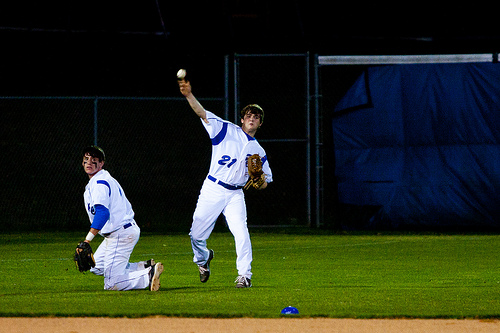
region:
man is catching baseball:
[167, 48, 274, 273]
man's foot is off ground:
[190, 231, 229, 293]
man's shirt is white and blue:
[204, 108, 256, 193]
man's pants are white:
[178, 174, 265, 274]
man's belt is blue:
[193, 159, 255, 197]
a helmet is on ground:
[273, 283, 298, 325]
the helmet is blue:
[268, 301, 312, 324]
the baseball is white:
[170, 51, 197, 91]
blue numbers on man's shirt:
[215, 146, 241, 171]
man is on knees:
[53, 151, 155, 315]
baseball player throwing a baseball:
[166, 52, 290, 293]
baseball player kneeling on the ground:
[63, 129, 191, 308]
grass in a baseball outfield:
[54, 227, 481, 308]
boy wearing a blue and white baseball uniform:
[169, 50, 297, 274]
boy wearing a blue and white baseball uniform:
[65, 110, 174, 305]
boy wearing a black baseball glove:
[61, 135, 171, 306]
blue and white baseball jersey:
[191, 62, 300, 274]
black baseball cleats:
[179, 231, 275, 301]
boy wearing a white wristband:
[66, 137, 136, 277]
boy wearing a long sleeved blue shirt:
[72, 137, 147, 279]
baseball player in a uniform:
[136, 48, 308, 292]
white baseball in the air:
[166, 56, 196, 79]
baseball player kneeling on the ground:
[51, 133, 171, 292]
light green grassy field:
[72, 213, 472, 319]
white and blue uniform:
[178, 85, 288, 291]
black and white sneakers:
[194, 242, 250, 312]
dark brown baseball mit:
[234, 146, 281, 199]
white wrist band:
[68, 218, 119, 270]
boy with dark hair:
[65, 134, 126, 193]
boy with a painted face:
[54, 136, 118, 199]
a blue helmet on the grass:
[269, 296, 308, 322]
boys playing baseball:
[39, 57, 288, 279]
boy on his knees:
[44, 140, 171, 291]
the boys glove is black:
[51, 234, 111, 280]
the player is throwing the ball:
[146, 45, 283, 308]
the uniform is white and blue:
[149, 61, 299, 291]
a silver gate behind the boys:
[66, 37, 327, 262]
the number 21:
[197, 142, 242, 184]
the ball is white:
[155, 57, 194, 112]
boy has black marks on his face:
[65, 137, 102, 174]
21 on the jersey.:
[216, 144, 248, 179]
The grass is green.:
[302, 240, 434, 308]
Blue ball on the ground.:
[266, 290, 312, 329]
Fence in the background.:
[8, 93, 185, 239]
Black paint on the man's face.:
[74, 148, 114, 182]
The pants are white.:
[189, 182, 253, 272]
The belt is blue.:
[203, 167, 251, 199]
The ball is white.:
[163, 64, 197, 91]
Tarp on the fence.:
[345, 73, 499, 226]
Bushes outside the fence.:
[21, 117, 203, 229]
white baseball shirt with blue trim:
[80, 166, 155, 241]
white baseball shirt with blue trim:
[198, 109, 272, 191]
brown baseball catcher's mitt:
[245, 155, 265, 183]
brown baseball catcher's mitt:
[71, 240, 96, 273]